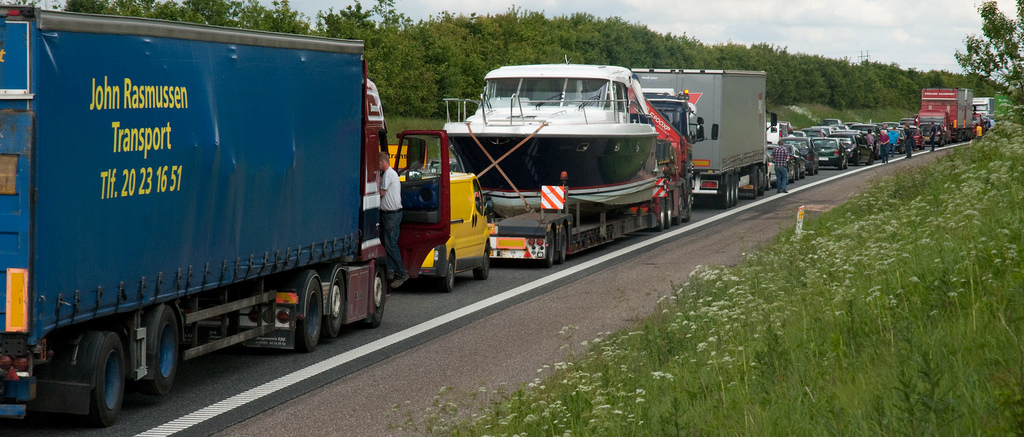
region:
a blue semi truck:
[0, 9, 399, 390]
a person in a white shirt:
[370, 157, 406, 287]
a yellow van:
[414, 170, 506, 284]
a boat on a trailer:
[468, 53, 665, 183]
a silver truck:
[645, 72, 764, 172]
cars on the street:
[761, 110, 986, 159]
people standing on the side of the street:
[855, 126, 926, 149]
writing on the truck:
[87, 85, 187, 204]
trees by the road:
[345, 21, 943, 99]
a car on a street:
[404, 162, 494, 298]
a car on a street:
[805, 127, 829, 170]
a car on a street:
[808, 124, 860, 164]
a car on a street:
[887, 105, 916, 144]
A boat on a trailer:
[443, 56, 662, 211]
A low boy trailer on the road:
[482, 198, 678, 262]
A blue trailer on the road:
[16, 6, 353, 418]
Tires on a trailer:
[48, 328, 135, 426]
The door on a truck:
[392, 129, 451, 279]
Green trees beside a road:
[17, 3, 1021, 106]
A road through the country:
[5, 116, 990, 433]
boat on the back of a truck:
[441, 63, 704, 263]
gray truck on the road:
[637, 65, 787, 205]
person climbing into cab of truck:
[374, 147, 407, 285]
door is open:
[384, 127, 457, 280]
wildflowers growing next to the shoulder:
[382, 114, 1021, 434]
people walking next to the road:
[849, 118, 944, 166]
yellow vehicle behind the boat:
[401, 169, 500, 293]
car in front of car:
[780, 133, 851, 173]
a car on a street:
[801, 127, 860, 163]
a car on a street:
[881, 111, 907, 150]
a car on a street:
[890, 123, 922, 150]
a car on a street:
[916, 113, 939, 140]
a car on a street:
[925, 107, 954, 133]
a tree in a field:
[945, 7, 1021, 116]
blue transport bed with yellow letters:
[0, 17, 370, 338]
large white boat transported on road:
[442, 62, 690, 203]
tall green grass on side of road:
[420, 116, 1022, 434]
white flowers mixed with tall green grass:
[402, 123, 1022, 433]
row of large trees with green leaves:
[32, 2, 1007, 119]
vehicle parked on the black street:
[0, 5, 413, 407]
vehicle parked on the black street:
[440, 55, 685, 258]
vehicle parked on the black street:
[772, 119, 817, 189]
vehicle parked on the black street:
[803, 122, 851, 183]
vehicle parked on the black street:
[844, 128, 880, 167]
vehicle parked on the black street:
[879, 109, 905, 163]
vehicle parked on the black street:
[914, 82, 984, 152]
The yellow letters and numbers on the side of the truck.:
[75, 66, 193, 209]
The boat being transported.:
[431, 66, 681, 196]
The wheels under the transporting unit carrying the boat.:
[517, 202, 696, 257]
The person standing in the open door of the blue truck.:
[377, 152, 409, 274]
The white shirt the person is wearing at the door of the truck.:
[382, 176, 402, 206]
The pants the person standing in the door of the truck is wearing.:
[381, 206, 408, 283]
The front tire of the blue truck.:
[363, 268, 389, 319]